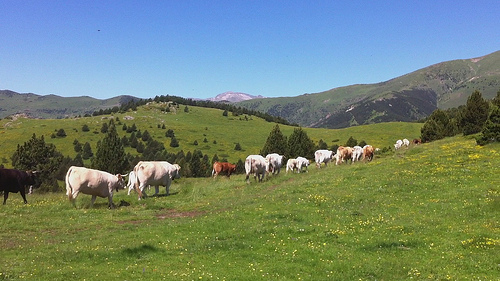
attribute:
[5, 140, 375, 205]
cows — a herd, walking